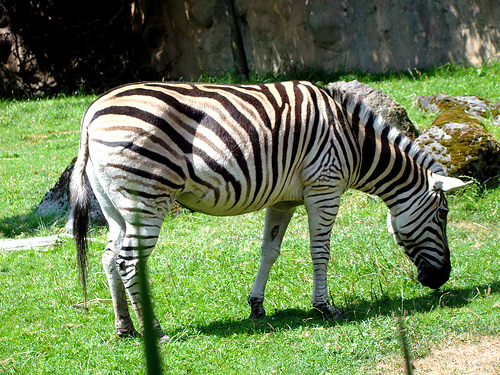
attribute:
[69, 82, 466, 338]
zebra — black, white, grazing, standing, striped, furry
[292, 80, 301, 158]
stripe — black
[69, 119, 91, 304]
tail — bushy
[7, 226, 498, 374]
grass — landscape, green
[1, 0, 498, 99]
wall — stone, rocky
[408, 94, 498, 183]
rock — flat, large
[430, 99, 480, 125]
moss — green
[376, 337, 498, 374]
grass — brown